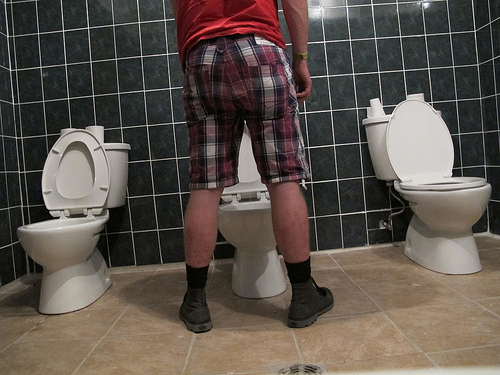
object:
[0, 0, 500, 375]
toilet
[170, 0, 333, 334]
man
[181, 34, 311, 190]
shorts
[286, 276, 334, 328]
shoe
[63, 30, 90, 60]
tile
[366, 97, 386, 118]
toilet paper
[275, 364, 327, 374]
drain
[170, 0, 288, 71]
shirt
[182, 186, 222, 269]
legs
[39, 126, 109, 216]
seat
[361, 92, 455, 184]
tank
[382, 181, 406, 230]
hose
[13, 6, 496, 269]
wall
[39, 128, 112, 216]
toilet seat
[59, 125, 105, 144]
toilet paper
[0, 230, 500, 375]
floor